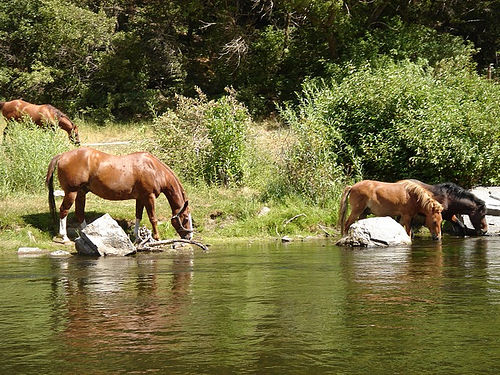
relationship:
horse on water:
[334, 180, 444, 243] [0, 242, 485, 372]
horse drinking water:
[45, 146, 194, 241] [0, 242, 485, 372]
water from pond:
[0, 242, 485, 372] [40, 225, 455, 346]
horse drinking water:
[334, 180, 444, 243] [0, 242, 485, 372]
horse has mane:
[393, 175, 486, 246] [440, 183, 480, 203]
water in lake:
[0, 242, 485, 372] [2, 251, 497, 373]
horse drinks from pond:
[334, 180, 444, 243] [0, 237, 497, 371]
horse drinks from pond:
[393, 175, 486, 246] [0, 237, 497, 371]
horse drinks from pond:
[45, 146, 194, 241] [0, 237, 497, 371]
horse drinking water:
[393, 175, 486, 246] [12, 239, 483, 362]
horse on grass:
[0, 97, 81, 149] [5, 103, 331, 250]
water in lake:
[0, 242, 485, 372] [328, 253, 394, 277]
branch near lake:
[134, 226, 206, 251] [3, 232, 497, 371]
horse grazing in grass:
[0, 97, 81, 149] [4, 117, 345, 229]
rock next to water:
[74, 212, 137, 255] [0, 242, 485, 372]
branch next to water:
[134, 226, 206, 251] [0, 242, 485, 372]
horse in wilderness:
[0, 97, 81, 149] [0, 0, 500, 373]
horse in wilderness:
[45, 146, 194, 241] [0, 0, 500, 373]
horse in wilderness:
[334, 180, 444, 243] [0, 0, 500, 373]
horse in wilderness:
[393, 175, 486, 246] [0, 0, 500, 373]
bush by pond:
[129, 84, 257, 186] [40, 225, 455, 346]